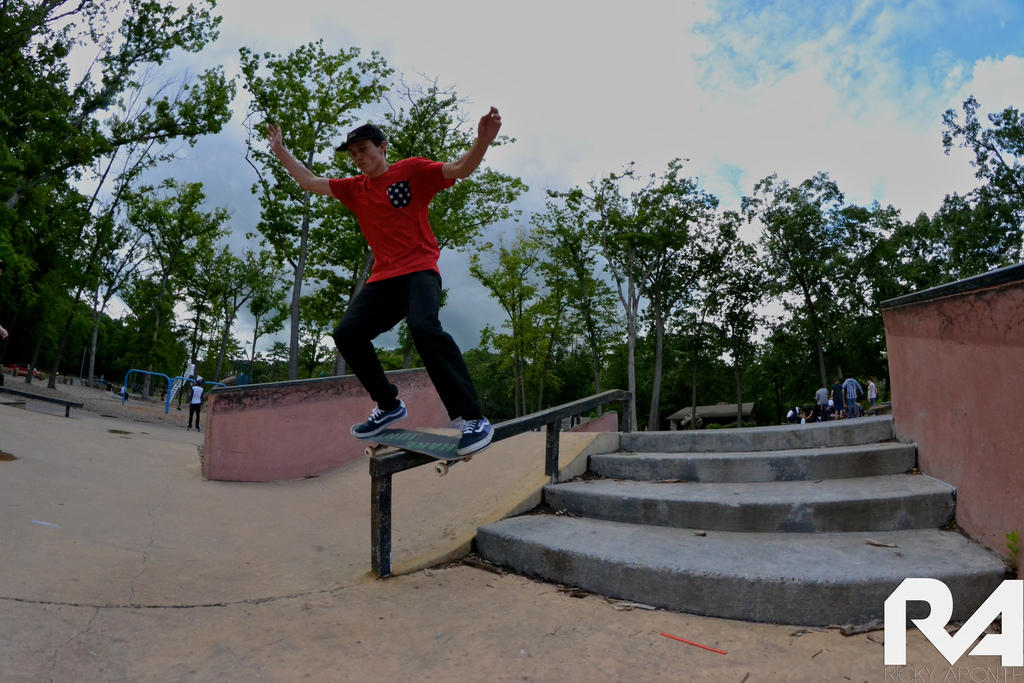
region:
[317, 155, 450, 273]
The red t-shirt the guy is wearing.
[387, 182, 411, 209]
The black and white pocket design on the guy's shirt.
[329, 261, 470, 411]
The black pants the guy is wearing.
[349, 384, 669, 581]
The black railing the guy is skateboarding on.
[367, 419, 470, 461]
The skateboard the guy is using to ride on the rail.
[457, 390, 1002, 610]
The gray stairs next to the black rail.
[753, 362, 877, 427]
The group of people standing in the distance.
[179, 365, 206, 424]
The person standing on the left in a white t-shirt.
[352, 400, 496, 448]
The black sneakers the skateboarder is wearing.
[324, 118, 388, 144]
The black hat the guy in the red shirt is wearing.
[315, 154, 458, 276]
man wearing a red shirt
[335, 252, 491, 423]
man wearing black pants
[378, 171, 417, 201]
black pocket on the shirt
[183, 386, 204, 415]
Man wearing a white shirt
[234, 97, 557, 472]
man doing a trick on a skateboard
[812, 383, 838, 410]
man wearing a gray shirt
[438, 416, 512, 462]
blue shoe on left foot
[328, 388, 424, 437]
blue shoe on right foot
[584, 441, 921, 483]
step on stair case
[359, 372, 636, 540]
railing on the stair case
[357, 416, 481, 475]
skateboard on the rail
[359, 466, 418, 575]
pole under the rail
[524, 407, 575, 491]
pole under the rail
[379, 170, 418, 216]
black pocket on shirt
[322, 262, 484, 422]
black pants on skater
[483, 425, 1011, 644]
The stairway steps to a park.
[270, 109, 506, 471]
The roller skater wearing red shirt.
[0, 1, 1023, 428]
The green vegetation in the background.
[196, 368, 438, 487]
The pink wall column on the ramp.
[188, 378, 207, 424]
The female person near the blue goal posts.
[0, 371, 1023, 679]
A gray cemented grounds.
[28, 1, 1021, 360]
A relatively clouded sky.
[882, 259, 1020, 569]
The pink colored wall column on the right.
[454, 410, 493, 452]
a black and white athletic shoe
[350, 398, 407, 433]
a black and white athletic shoe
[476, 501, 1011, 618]
A step on a stairway.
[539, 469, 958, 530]
A step on a stairway.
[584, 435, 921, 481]
A step on a stairway.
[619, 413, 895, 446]
A step on a stairway.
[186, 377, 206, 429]
A person is standing up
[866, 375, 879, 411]
A person is standing up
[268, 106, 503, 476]
a person is skateboarding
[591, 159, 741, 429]
A tree in a park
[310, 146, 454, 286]
Red t-shirt with black and white pocket.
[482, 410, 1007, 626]
Four concrete steps.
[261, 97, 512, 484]
A boy on a skateboard with his hands in the air.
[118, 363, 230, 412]
Two blue rails.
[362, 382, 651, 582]
A rail with a skateboard on it.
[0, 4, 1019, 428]
Leafy green trees against a cloudy blue sky.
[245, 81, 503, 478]
Young man riding skateboard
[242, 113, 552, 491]
Young man in red shirt on rail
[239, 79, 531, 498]
young man in red shirt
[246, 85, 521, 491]
young man in red shirt on board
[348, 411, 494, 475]
skateboard on pipe rail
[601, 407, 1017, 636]
four concrete stair steps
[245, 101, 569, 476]
young man in black pants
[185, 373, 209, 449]
young man in white shirt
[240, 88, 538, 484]
young man in red shirt riding rail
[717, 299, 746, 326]
green leaves on the tree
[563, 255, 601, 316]
green leaves on the tree